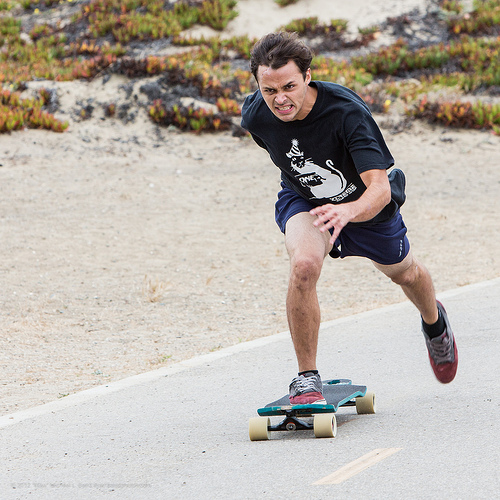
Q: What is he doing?
A: Skating.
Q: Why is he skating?
A: For sport.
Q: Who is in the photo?
A: A boy.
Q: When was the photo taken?
A: Daytime.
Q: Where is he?
A: On the street.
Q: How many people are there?
A: One.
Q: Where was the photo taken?
A: In a street.